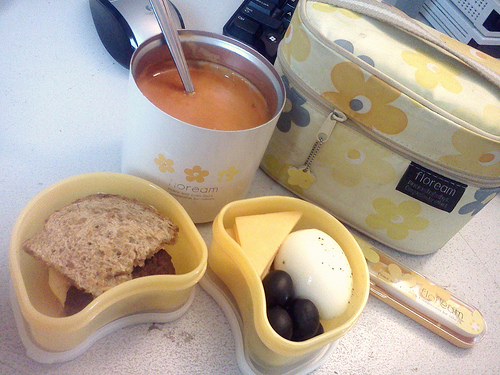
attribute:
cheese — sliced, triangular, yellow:
[231, 209, 304, 281]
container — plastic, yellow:
[208, 194, 370, 369]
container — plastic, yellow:
[7, 170, 209, 353]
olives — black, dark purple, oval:
[265, 270, 324, 340]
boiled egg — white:
[273, 229, 352, 319]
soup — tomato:
[139, 55, 270, 130]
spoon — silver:
[149, 0, 194, 94]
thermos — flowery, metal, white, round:
[125, 28, 287, 225]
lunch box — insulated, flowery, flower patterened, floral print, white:
[260, 1, 499, 258]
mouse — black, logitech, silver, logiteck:
[89, 0, 185, 70]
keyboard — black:
[224, 1, 300, 65]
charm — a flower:
[286, 166, 316, 195]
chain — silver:
[304, 136, 324, 175]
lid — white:
[199, 267, 339, 372]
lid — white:
[8, 279, 198, 366]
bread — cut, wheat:
[23, 195, 180, 298]